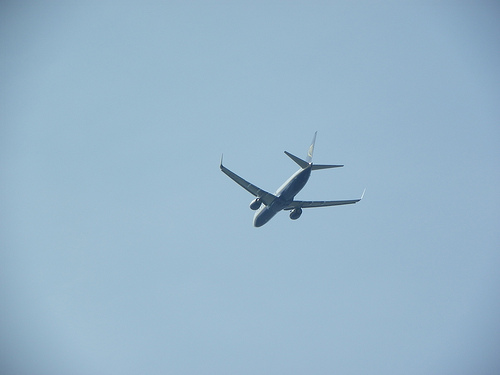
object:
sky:
[1, 0, 499, 373]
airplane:
[217, 133, 365, 226]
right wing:
[284, 188, 365, 209]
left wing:
[220, 154, 274, 206]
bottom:
[254, 167, 310, 224]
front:
[254, 205, 277, 227]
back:
[276, 132, 345, 198]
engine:
[289, 208, 302, 220]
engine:
[249, 197, 262, 210]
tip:
[284, 131, 343, 171]